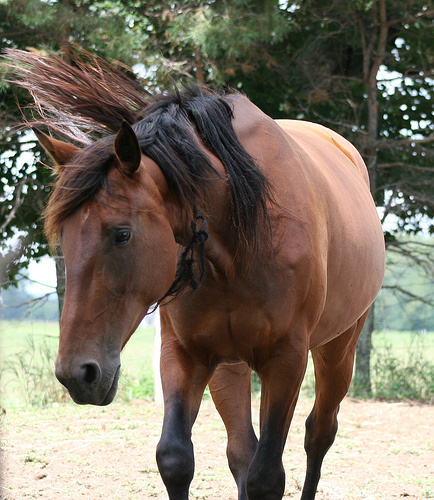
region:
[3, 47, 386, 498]
a dark brown horse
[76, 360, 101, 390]
dark nostril on horse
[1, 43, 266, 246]
black and brown mane flying in the air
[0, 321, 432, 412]
green grass behind horse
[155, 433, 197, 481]
knobby knee on horse leg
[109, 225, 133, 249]
the soulful eye of a wise horse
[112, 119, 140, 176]
cute little horse ear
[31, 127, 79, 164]
the horse's light brown right ear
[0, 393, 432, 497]
dry brown ground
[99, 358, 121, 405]
a black mouth on a horse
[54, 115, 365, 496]
brown horse with four legs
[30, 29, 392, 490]
a brown and black horse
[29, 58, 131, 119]
brown hair blowing in the wind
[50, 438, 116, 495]
dirt on the ground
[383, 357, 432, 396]
a small green bush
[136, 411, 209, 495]
a black knee on a horse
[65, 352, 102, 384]
a nostril on a snout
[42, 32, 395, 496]
a horse trotting in a pasture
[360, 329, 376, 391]
the gray bark on a tree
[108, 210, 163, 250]
the black eye on a horse head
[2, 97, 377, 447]
this is a horse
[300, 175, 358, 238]
the horse is brown in color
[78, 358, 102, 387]
this is the nose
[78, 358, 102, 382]
the nose is big in size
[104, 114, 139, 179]
this is the ear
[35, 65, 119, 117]
the fur are wavy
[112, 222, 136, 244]
the eye is black in color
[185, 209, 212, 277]
this is a belt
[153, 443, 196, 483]
the knee is black in color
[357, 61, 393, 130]
the tree is branchy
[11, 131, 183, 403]
the horse looks serious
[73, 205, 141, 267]
the horses eye is brown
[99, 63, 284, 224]
the horse mane is black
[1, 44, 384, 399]
the horse is brown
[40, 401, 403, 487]
the dirt is light brown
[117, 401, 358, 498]
the bottom of the legs are darker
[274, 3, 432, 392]
the tree is behind the horse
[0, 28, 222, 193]
the mane is blowing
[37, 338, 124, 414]
the nose is a darker color than the body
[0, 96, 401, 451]
the horse is free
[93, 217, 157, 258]
small brown eye of the horse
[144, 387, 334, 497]
black legs on the horse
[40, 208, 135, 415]
brown horses snout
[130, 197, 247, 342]
rope around the horse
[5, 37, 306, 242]
horse flicking its hair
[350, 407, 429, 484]
dirty ground with leaves and sticks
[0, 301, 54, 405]
green pasture behind the horse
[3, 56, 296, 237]
black and brown horse mane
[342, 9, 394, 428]
tall brown tree behind the horse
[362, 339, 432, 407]
green bushes in the background